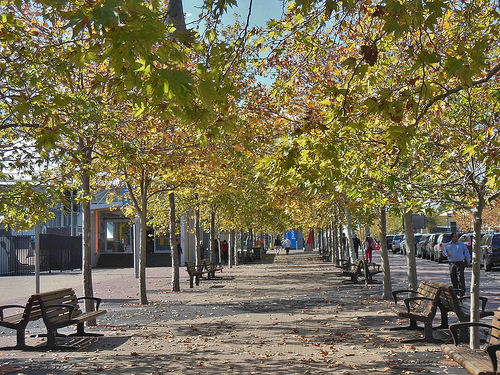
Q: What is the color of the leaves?
A: Green.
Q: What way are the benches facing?
A: Inwards.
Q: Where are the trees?
A: On both sides of the road.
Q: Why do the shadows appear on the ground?
A: It is a sunny day.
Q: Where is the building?
A: Behind the trees.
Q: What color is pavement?
A: Gray.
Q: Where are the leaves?
A: On pavement.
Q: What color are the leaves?
A: Brown and green.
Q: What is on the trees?
A: Leaves.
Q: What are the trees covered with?
A: Leaves.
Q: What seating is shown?
A: Benches.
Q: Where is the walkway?
A: Beneath trees.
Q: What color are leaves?
A: Green.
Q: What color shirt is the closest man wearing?
A: Blue.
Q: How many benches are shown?
A: 9.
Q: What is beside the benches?
A: Trees.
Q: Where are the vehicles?
A: Right side of the image.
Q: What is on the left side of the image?
A: Building.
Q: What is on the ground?
A: Leaves.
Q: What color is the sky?
A: Blue.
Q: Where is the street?
A: Right side.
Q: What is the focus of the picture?
A: Pathway.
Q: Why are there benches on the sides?
A: For resting.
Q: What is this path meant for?
A: Walking.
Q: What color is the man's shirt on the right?
A: Blue.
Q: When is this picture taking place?
A: Daytime.